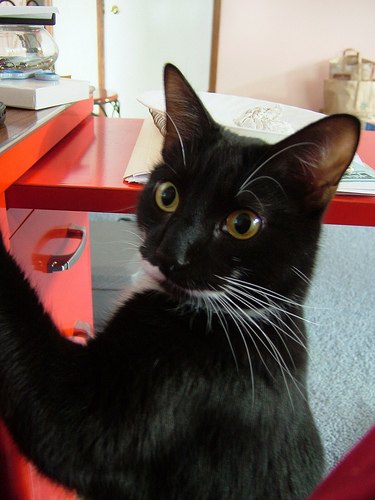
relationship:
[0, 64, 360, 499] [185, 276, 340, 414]
cat has whiskers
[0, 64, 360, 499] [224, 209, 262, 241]
cat has eye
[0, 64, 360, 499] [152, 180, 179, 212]
cat has eye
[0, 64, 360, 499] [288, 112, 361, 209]
cat has ear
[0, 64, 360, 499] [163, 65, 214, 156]
cat has ear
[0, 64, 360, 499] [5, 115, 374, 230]
cat next to desk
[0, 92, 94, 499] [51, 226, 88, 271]
dresser has handle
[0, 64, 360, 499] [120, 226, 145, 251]
cat has whiskers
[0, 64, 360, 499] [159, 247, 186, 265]
cat has nose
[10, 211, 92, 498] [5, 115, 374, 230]
drawer below desk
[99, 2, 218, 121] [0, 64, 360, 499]
door behind cat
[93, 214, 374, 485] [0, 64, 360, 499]
carpet under cat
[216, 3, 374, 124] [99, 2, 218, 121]
wall next to door